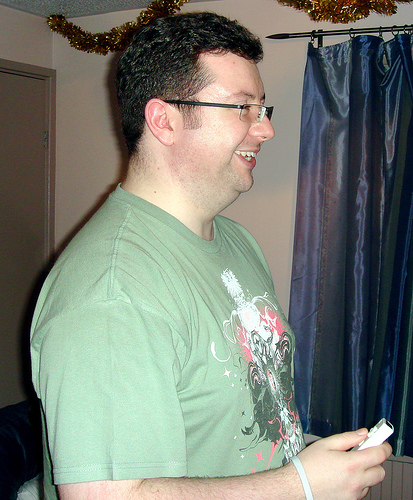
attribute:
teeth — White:
[233, 149, 257, 162]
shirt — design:
[35, 185, 342, 485]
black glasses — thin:
[148, 92, 291, 134]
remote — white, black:
[343, 413, 391, 448]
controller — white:
[358, 415, 394, 452]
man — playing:
[41, 27, 360, 493]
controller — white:
[345, 417, 393, 450]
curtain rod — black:
[264, 22, 411, 39]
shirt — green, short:
[29, 182, 308, 498]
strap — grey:
[288, 452, 309, 497]